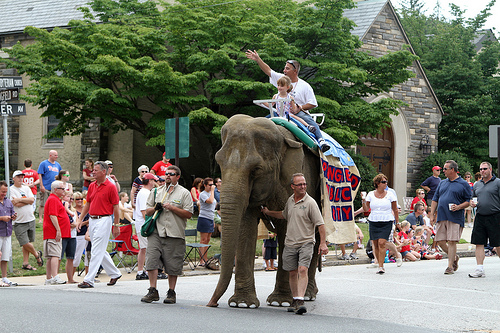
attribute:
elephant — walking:
[205, 113, 359, 307]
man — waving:
[244, 50, 331, 153]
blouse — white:
[366, 189, 397, 221]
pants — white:
[77, 215, 122, 289]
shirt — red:
[86, 178, 119, 212]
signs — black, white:
[0, 73, 29, 200]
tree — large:
[4, 2, 417, 211]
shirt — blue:
[432, 177, 471, 225]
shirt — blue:
[38, 160, 64, 191]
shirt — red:
[42, 193, 71, 241]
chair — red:
[114, 224, 142, 274]